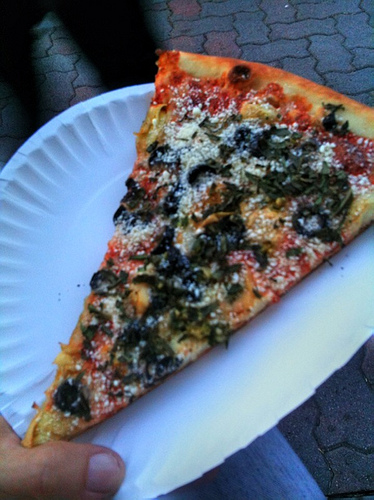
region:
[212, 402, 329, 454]
edge of white paper plate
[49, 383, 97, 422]
olive on cheese pizza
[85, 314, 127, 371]
white cheese on pizza slice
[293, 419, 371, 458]
brick ground of park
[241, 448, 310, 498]
blue jeans of man eating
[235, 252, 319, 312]
red sauce of slice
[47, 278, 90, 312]
crumbs of pizza slice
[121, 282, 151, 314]
cheese of slice of pizza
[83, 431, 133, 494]
thumb fingernail of man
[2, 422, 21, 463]
white skin of man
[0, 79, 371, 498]
a white paper plate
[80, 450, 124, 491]
a thumbnail holding a plate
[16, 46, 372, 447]
a slice of pizza on a plate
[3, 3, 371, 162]
a brick paved walkway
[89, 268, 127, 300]
a black olive slice on pizza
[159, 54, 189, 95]
red sauce on pizza crust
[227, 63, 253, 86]
a brown bubble on pizza crust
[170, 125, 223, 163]
grated Parmesan cheese on top of pizza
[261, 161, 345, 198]
green herbs on a slice of pizza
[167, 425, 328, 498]
a wood table under a plate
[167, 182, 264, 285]
toppings on pizza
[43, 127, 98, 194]
scalloped edge of paper plate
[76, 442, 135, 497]
broken short thumb nail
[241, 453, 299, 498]
blue denim jeans on person's leg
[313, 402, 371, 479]
cracked brick textured gray ground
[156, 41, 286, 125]
crust of the pizza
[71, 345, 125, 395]
ground Parmesan cheese on pizza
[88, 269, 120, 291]
black olives as topping on pizza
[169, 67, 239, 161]
sauce on the pizza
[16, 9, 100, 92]
shadows on the brick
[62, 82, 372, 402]
SLICE OF PIZZA ON WHITE PAPER PLATE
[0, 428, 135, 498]
LEFT THUMB OF CAUCASIAN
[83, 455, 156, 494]
LEFT THUMB NAIL ON HAND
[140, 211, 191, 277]
GREEN SPINACH ON SLICE OF PIZZA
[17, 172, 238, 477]
WHITE PAPER PLATE IN MAN'S HAND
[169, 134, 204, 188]
PARMESIAN CHEESE ON SLICE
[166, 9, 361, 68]
PINK AND GREY BRICKS ON GROUND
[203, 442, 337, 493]
BLUE DENIM JEANS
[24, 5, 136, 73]
SHADOW OF OBJECT ON RIGHT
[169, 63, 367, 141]
TOMATO SAUCE ON SLICE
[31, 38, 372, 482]
One slice of pizza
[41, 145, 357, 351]
pizza has black olives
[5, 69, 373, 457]
pizza on a white plate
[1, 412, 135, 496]
Thumb on a plate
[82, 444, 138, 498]
finger nail of thumb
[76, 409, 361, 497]
blue jeans under plate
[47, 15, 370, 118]
red and black ground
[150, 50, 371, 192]
Crust of the pizza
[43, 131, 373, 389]
Cheese on the pizza